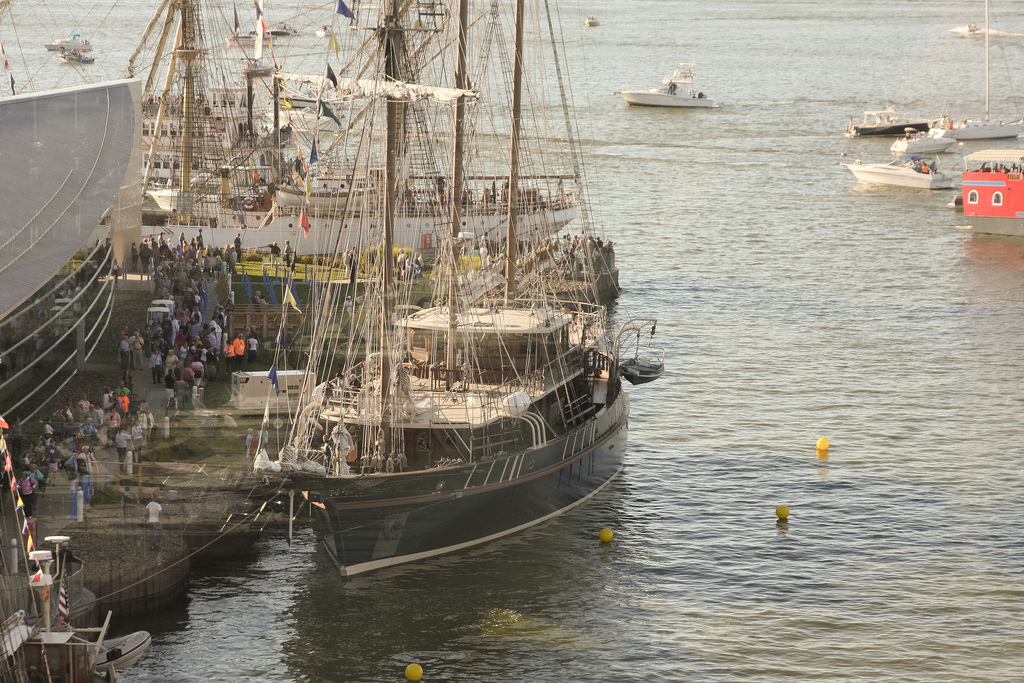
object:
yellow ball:
[405, 664, 424, 681]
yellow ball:
[599, 527, 615, 541]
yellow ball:
[777, 505, 791, 519]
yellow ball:
[816, 437, 830, 450]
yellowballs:
[775, 437, 829, 518]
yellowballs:
[599, 436, 831, 541]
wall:
[321, 304, 592, 467]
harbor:
[0, 0, 1024, 683]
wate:
[621, 0, 1024, 683]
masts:
[381, 1, 524, 474]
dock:
[0, 247, 488, 679]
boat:
[254, 0, 667, 578]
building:
[0, 79, 143, 437]